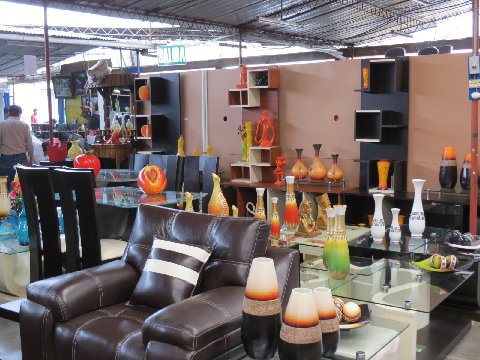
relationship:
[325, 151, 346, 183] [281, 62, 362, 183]
vase next to wall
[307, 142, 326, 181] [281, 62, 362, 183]
vase next to wall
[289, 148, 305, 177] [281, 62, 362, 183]
vase next to wall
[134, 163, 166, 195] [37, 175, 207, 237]
sculpture sitting on table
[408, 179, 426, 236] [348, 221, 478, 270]
vase sitting on table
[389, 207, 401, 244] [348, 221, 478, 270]
vase sitting on table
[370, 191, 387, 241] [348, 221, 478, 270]
vase sitting on table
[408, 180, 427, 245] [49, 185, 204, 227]
vase sitting on table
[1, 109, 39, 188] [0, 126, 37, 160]
man in shirt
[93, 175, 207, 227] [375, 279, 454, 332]
table with base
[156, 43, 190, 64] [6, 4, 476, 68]
sign hanging from rafters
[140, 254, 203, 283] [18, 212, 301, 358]
line in chair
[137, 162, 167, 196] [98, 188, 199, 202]
flower on table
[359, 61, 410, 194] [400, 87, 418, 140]
door in wall